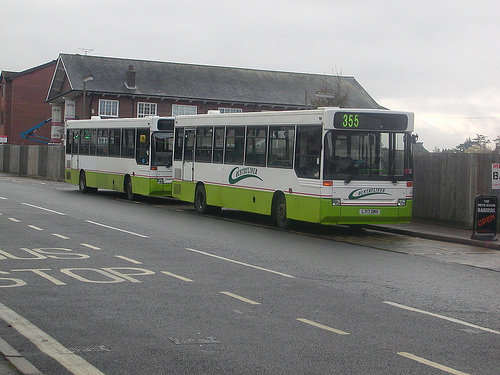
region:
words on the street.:
[12, 254, 102, 292]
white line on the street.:
[289, 322, 360, 339]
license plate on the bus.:
[353, 206, 383, 216]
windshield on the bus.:
[342, 140, 394, 162]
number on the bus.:
[337, 113, 362, 128]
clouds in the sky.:
[376, 30, 466, 74]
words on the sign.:
[477, 200, 493, 236]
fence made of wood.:
[422, 160, 473, 213]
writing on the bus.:
[220, 170, 270, 180]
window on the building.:
[95, 102, 117, 112]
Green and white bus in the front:
[165, 100, 431, 235]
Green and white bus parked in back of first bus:
[50, 105, 175, 201]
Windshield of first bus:
[320, 125, 420, 195]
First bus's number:
[330, 105, 405, 130]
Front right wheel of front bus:
[250, 180, 300, 230]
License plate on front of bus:
[345, 195, 400, 225]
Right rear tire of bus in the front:
[177, 175, 217, 220]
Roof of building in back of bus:
[42, 50, 382, 110]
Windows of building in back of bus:
[86, 95, 176, 117]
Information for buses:
[0, 243, 159, 299]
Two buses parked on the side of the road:
[56, 100, 438, 255]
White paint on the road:
[48, 191, 313, 366]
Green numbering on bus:
[325, 100, 360, 132]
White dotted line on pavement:
[217, 272, 265, 322]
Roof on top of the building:
[55, 55, 382, 107]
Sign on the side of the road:
[467, 178, 498, 232]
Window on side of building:
[89, 91, 134, 141]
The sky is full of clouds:
[364, 23, 439, 95]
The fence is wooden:
[412, 152, 456, 217]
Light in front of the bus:
[325, 191, 345, 211]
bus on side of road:
[61, 101, 431, 241]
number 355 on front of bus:
[335, 107, 360, 124]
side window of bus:
[291, 125, 323, 180]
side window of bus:
[268, 123, 293, 173]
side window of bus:
[240, 124, 267, 174]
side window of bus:
[218, 123, 245, 168]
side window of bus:
[196, 126, 219, 163]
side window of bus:
[121, 133, 138, 158]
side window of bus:
[107, 127, 118, 151]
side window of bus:
[92, 129, 105, 154]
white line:
[288, 307, 368, 374]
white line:
[217, 261, 324, 352]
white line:
[208, 284, 305, 369]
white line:
[197, 231, 278, 333]